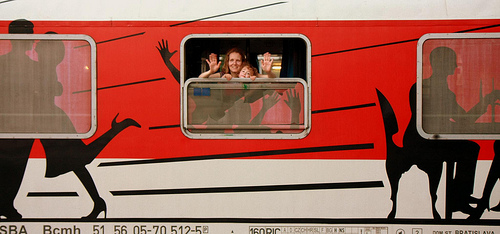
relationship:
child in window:
[221, 64, 260, 82] [176, 32, 311, 137]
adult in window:
[195, 50, 275, 77] [176, 32, 311, 137]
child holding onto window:
[194, 62, 256, 121] [176, 32, 311, 137]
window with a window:
[410, 25, 487, 141] [172, 26, 317, 148]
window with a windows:
[410, 25, 487, 141] [0, 33, 98, 141]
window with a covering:
[410, 25, 487, 141] [178, 76, 312, 139]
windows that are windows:
[22, 17, 499, 200] [0, 33, 98, 141]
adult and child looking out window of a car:
[198, 47, 278, 78] [0, 1, 498, 232]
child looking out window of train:
[221, 64, 260, 82] [124, 50, 345, 153]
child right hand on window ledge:
[221, 64, 260, 82] [185, 75, 300, 83]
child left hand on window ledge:
[221, 64, 260, 82] [178, 100, 280, 203]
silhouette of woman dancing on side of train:
[29, 29, 142, 222] [2, 2, 497, 232]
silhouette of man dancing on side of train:
[1, 15, 65, 222] [2, 2, 497, 232]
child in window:
[221, 64, 260, 82] [186, 24, 323, 129]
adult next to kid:
[198, 47, 278, 78] [235, 57, 259, 79]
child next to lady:
[221, 64, 260, 82] [201, 40, 248, 84]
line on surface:
[336, 95, 368, 120] [336, 51, 388, 103]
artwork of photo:
[0, 1, 500, 227] [54, 49, 491, 94]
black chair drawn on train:
[354, 94, 469, 224] [2, 2, 497, 232]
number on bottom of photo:
[151, 223, 205, 232] [2, 0, 498, 232]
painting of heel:
[107, 101, 140, 153] [108, 112, 144, 131]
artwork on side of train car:
[0, 1, 498, 224] [0, 1, 498, 232]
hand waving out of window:
[146, 31, 178, 78] [164, 50, 301, 192]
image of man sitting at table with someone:
[375, 46, 499, 220] [466, 139, 498, 221]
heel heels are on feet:
[108, 112, 144, 131] [74, 105, 154, 234]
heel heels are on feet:
[78, 97, 146, 212] [74, 105, 154, 234]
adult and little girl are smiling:
[198, 47, 278, 78] [192, 51, 270, 110]